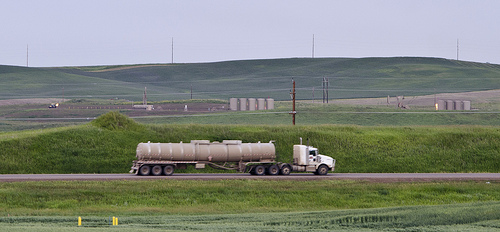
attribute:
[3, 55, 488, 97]
hills — green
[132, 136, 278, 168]
tank — oil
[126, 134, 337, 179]
truck — large, oil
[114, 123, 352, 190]
18 wheeler — driving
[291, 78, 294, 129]
pole — wooden, telephone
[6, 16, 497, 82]
poles — four more, telephone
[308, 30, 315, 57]
pole — tall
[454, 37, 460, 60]
pole — tall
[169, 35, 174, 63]
pole — tall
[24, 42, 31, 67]
pole — tall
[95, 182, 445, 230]
grass — refuse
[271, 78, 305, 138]
pole — brown, wooden, utility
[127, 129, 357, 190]
truck — large, tanker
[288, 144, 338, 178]
cab — white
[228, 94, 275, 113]
barrels — five, cylindrical, metal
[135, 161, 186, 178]
wheels — rear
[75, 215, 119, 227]
markers — small, yellow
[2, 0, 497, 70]
sky — hazy, blue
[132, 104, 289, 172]
tank — large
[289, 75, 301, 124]
pole — brown, utility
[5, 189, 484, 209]
grass — green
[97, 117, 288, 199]
trailer — large, tan, tanker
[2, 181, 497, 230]
grass — green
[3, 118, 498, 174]
grass — green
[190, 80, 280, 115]
pipes — vent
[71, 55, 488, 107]
hill — grass covered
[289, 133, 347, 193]
tractor — white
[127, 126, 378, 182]
truck — over the road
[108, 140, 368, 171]
tanker — trailer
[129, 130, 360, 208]
truck — tanker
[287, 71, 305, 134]
post — dark brown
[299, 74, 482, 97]
wires — electric